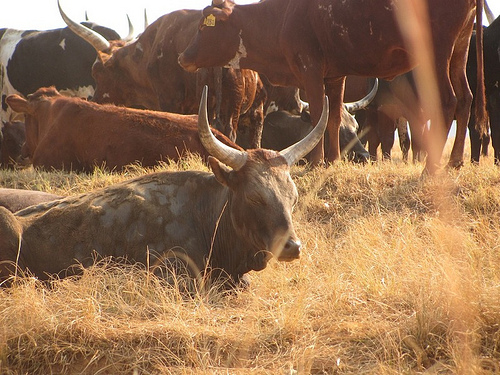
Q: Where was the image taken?
A: It was taken at the plain.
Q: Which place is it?
A: It is a plain.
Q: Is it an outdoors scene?
A: Yes, it is outdoors.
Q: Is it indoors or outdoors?
A: It is outdoors.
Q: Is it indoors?
A: No, it is outdoors.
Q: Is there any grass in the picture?
A: Yes, there is grass.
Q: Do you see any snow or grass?
A: Yes, there is grass.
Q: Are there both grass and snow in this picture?
A: No, there is grass but no snow.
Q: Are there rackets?
A: No, there are no rackets.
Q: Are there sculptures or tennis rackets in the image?
A: No, there are no tennis rackets or sculptures.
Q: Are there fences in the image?
A: No, there are no fences.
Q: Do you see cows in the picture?
A: Yes, there is a cow.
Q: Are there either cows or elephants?
A: Yes, there is a cow.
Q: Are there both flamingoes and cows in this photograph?
A: No, there is a cow but no flamingoes.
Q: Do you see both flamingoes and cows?
A: No, there is a cow but no flamingoes.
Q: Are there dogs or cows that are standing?
A: Yes, the cow is standing.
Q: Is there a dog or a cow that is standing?
A: Yes, the cow is standing.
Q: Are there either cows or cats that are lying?
A: Yes, the cow is lying.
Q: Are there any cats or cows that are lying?
A: Yes, the cow is lying.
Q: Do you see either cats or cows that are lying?
A: Yes, the cow is lying.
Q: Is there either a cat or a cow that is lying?
A: Yes, the cow is lying.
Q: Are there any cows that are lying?
A: Yes, there is a cow that is lying.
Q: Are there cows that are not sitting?
A: Yes, there is a cow that is lying.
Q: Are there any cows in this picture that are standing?
A: Yes, there is a cow that is standing.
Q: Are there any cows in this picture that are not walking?
A: Yes, there is a cow that is standing.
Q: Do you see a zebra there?
A: No, there are no zebras.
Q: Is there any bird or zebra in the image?
A: No, there are no zebras or birds.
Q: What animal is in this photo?
A: The animal is a cow.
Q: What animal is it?
A: The animal is a cow.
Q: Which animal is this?
A: That is a cow.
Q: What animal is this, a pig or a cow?
A: That is a cow.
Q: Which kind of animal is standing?
A: The animal is a cow.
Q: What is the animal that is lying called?
A: The animal is a cow.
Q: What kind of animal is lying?
A: The animal is a cow.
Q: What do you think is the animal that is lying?
A: The animal is a cow.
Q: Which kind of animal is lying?
A: The animal is a cow.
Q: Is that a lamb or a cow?
A: That is a cow.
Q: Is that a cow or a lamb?
A: That is a cow.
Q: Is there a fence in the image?
A: No, there are no fences.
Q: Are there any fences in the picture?
A: No, there are no fences.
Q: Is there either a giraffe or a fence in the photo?
A: No, there are no fences or giraffes.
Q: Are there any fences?
A: No, there are no fences.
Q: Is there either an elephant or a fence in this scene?
A: No, there are no fences or elephants.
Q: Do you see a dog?
A: No, there are no dogs.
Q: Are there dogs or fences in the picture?
A: No, there are no dogs or fences.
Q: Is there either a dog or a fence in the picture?
A: No, there are no dogs or fences.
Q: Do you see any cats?
A: No, there are no cats.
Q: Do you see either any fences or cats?
A: No, there are no cats or fences.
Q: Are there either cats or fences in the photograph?
A: No, there are no cats or fences.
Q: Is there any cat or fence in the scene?
A: No, there are no cats or fences.